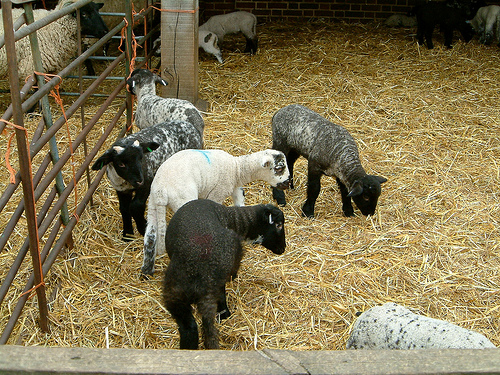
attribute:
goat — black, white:
[138, 150, 290, 280]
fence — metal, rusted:
[2, 1, 159, 344]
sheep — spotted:
[92, 120, 199, 243]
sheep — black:
[158, 197, 288, 347]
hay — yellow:
[1, 21, 496, 349]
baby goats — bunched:
[155, 4, 500, 62]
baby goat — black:
[415, 5, 475, 51]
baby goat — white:
[466, 4, 499, 44]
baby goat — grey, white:
[124, 70, 206, 142]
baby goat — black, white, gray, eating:
[269, 104, 387, 219]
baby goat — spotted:
[342, 300, 499, 349]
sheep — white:
[0, 1, 110, 92]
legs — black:
[272, 145, 352, 218]